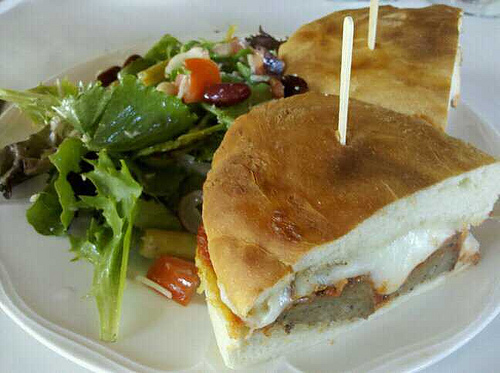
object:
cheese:
[349, 230, 424, 273]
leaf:
[23, 134, 80, 237]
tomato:
[144, 254, 199, 307]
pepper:
[179, 57, 221, 104]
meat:
[392, 232, 464, 296]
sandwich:
[193, 91, 499, 368]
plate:
[0, 33, 499, 373]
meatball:
[240, 274, 413, 345]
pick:
[330, 122, 356, 163]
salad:
[1, 37, 268, 240]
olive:
[275, 72, 310, 97]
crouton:
[166, 19, 261, 109]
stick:
[319, 13, 376, 149]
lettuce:
[47, 79, 190, 201]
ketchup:
[335, 272, 400, 345]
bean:
[204, 79, 254, 109]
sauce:
[376, 280, 391, 294]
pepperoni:
[160, 48, 247, 131]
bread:
[197, 90, 499, 314]